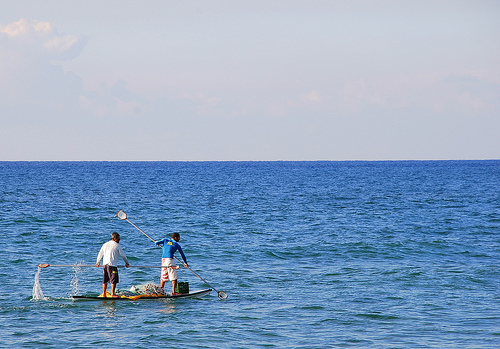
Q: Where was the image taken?
A: It was taken at the ocean.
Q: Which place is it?
A: It is an ocean.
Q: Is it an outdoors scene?
A: Yes, it is outdoors.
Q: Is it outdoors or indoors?
A: It is outdoors.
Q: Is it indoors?
A: No, it is outdoors.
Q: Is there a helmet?
A: No, there are no helmets.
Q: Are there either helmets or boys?
A: No, there are no helmets or boys.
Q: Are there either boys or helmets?
A: No, there are no helmets or boys.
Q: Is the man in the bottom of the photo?
A: Yes, the man is in the bottom of the image.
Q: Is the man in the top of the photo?
A: No, the man is in the bottom of the image.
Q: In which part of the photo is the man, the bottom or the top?
A: The man is in the bottom of the image.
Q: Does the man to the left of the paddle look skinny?
A: Yes, the man is skinny.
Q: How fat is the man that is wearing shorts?
A: The man is skinny.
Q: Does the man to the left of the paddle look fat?
A: No, the man is skinny.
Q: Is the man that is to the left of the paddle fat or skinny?
A: The man is skinny.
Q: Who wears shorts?
A: The man wears shorts.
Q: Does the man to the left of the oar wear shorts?
A: Yes, the man wears shorts.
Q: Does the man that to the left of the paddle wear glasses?
A: No, the man wears shorts.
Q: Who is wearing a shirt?
A: The man is wearing a shirt.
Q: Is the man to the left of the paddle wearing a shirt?
A: Yes, the man is wearing a shirt.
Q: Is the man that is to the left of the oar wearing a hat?
A: No, the man is wearing a shirt.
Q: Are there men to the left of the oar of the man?
A: Yes, there is a man to the left of the oar.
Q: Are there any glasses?
A: No, there are no glasses.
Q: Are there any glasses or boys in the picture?
A: No, there are no glasses or boys.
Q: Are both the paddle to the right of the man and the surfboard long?
A: Yes, both the oar and the surfboard are long.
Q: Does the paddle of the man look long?
A: Yes, the paddle is long.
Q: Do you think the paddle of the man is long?
A: Yes, the paddle is long.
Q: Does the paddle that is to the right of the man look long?
A: Yes, the oar is long.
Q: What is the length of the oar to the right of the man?
A: The oar is long.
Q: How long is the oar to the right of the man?
A: The oar is long.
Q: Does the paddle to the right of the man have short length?
A: No, the oar is long.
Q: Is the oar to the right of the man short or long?
A: The paddle is long.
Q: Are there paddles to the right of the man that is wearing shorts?
A: Yes, there is a paddle to the right of the man.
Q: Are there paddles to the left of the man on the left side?
A: No, the paddle is to the right of the man.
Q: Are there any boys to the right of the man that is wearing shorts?
A: No, there is a paddle to the right of the man.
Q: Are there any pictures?
A: No, there are no pictures.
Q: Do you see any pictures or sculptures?
A: No, there are no pictures or sculptures.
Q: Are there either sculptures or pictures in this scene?
A: No, there are no pictures or sculptures.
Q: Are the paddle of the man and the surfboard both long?
A: Yes, both the paddle and the surfboard are long.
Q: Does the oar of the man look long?
A: Yes, the paddle is long.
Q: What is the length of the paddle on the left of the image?
A: The paddle is long.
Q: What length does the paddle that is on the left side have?
A: The paddle has long length.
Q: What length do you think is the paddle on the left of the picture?
A: The paddle is long.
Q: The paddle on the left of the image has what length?
A: The paddle is long.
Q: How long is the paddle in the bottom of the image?
A: The paddle is long.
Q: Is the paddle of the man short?
A: No, the oar is long.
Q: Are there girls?
A: No, there are no girls.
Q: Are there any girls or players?
A: No, there are no girls or players.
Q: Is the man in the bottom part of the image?
A: Yes, the man is in the bottom of the image.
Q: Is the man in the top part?
A: No, the man is in the bottom of the image.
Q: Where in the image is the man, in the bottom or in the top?
A: The man is in the bottom of the image.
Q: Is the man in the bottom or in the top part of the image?
A: The man is in the bottom of the image.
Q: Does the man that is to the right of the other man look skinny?
A: Yes, the man is skinny.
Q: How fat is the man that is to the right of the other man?
A: The man is skinny.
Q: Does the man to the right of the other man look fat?
A: No, the man is skinny.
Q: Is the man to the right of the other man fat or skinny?
A: The man is skinny.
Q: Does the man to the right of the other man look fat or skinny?
A: The man is skinny.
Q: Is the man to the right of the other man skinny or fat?
A: The man is skinny.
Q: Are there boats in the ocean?
A: No, there is a man in the ocean.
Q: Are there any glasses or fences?
A: No, there are no glasses or fences.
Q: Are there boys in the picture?
A: No, there are no boys.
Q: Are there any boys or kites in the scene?
A: No, there are no boys or kites.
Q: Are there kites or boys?
A: No, there are no boys or kites.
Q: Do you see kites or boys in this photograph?
A: No, there are no boys or kites.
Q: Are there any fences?
A: No, there are no fences.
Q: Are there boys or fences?
A: No, there are no fences or boys.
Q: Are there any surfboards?
A: Yes, there is a surfboard.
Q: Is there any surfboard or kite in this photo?
A: Yes, there is a surfboard.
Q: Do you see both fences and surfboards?
A: No, there is a surfboard but no fences.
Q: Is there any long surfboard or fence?
A: Yes, there is a long surfboard.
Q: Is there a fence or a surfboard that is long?
A: Yes, the surfboard is long.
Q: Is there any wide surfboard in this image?
A: Yes, there is a wide surfboard.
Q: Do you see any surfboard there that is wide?
A: Yes, there is a surfboard that is wide.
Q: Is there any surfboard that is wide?
A: Yes, there is a surfboard that is wide.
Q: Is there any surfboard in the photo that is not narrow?
A: Yes, there is a wide surfboard.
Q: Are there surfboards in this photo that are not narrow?
A: Yes, there is a wide surfboard.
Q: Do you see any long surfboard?
A: Yes, there is a long surfboard.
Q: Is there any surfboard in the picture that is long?
A: Yes, there is a surfboard that is long.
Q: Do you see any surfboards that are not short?
A: Yes, there is a long surfboard.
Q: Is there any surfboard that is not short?
A: Yes, there is a long surfboard.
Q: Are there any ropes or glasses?
A: No, there are no glasses or ropes.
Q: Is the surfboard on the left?
A: Yes, the surfboard is on the left of the image.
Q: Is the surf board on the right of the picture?
A: No, the surf board is on the left of the image.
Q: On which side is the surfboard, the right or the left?
A: The surfboard is on the left of the image.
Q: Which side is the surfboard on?
A: The surfboard is on the left of the image.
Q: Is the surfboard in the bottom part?
A: Yes, the surfboard is in the bottom of the image.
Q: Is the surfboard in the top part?
A: No, the surfboard is in the bottom of the image.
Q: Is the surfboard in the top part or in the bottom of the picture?
A: The surfboard is in the bottom of the image.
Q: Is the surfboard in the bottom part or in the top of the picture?
A: The surfboard is in the bottom of the image.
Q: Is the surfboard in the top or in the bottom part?
A: The surfboard is in the bottom of the image.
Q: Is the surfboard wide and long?
A: Yes, the surfboard is wide and long.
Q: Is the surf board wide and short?
A: No, the surf board is wide but long.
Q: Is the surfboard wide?
A: Yes, the surfboard is wide.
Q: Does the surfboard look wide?
A: Yes, the surfboard is wide.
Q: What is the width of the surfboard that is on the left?
A: The surfboard is wide.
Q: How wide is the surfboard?
A: The surfboard is wide.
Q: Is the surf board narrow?
A: No, the surf board is wide.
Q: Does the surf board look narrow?
A: No, the surf board is wide.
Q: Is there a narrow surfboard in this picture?
A: No, there is a surfboard but it is wide.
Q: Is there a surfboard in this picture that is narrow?
A: No, there is a surfboard but it is wide.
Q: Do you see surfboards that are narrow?
A: No, there is a surfboard but it is wide.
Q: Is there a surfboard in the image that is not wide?
A: No, there is a surfboard but it is wide.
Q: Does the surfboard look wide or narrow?
A: The surfboard is wide.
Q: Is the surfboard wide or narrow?
A: The surfboard is wide.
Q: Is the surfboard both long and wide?
A: Yes, the surfboard is long and wide.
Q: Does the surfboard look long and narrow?
A: No, the surfboard is long but wide.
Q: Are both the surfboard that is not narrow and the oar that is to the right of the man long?
A: Yes, both the surfboard and the oar are long.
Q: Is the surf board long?
A: Yes, the surf board is long.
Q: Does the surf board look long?
A: Yes, the surf board is long.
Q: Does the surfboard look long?
A: Yes, the surfboard is long.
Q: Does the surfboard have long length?
A: Yes, the surfboard is long.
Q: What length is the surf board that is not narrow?
A: The surfboard is long.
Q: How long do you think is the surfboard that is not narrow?
A: The surf board is long.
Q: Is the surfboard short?
A: No, the surfboard is long.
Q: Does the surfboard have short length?
A: No, the surfboard is long.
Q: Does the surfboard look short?
A: No, the surfboard is long.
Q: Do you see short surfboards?
A: No, there is a surfboard but it is long.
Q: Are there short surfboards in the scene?
A: No, there is a surfboard but it is long.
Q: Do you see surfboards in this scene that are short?
A: No, there is a surfboard but it is long.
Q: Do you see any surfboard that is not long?
A: No, there is a surfboard but it is long.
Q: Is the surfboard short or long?
A: The surfboard is long.